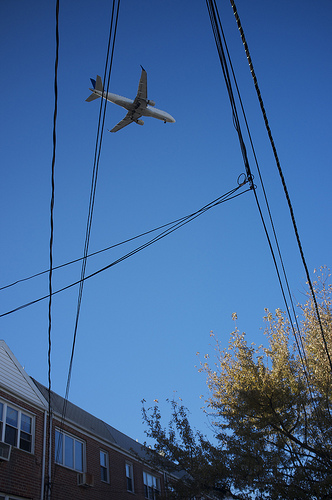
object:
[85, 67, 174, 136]
airplane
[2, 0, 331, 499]
sky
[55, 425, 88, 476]
window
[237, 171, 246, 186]
wiring loops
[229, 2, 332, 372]
wires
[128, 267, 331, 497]
tree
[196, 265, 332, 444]
sunlight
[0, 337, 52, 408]
siding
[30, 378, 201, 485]
roof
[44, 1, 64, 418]
wires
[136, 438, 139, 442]
chimneys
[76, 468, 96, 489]
air conditioning uni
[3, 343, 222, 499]
building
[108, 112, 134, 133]
wings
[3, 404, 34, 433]
blinds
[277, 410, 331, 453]
branch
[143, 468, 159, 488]
window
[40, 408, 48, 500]
drainage pipe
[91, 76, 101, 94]
tail fin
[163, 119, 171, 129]
front wheel